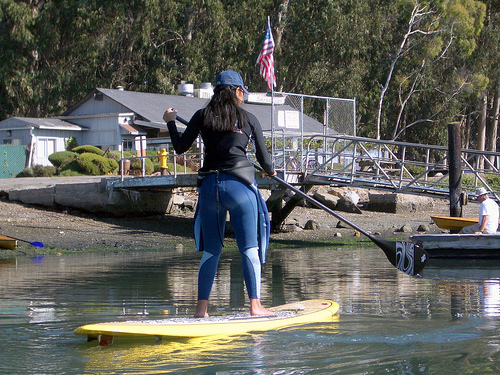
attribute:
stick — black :
[165, 106, 430, 278]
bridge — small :
[262, 131, 499, 206]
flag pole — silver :
[263, 20, 282, 171]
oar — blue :
[29, 240, 49, 249]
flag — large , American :
[254, 15, 283, 90]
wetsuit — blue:
[194, 168, 271, 303]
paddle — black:
[77, 288, 340, 343]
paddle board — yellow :
[66, 287, 354, 349]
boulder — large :
[367, 187, 436, 212]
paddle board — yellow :
[71, 292, 341, 343]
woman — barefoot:
[160, 67, 287, 327]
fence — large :
[268, 77, 356, 165]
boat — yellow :
[426, 210, 498, 232]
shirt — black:
[168, 94, 292, 186]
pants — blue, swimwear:
[191, 171, 258, 305]